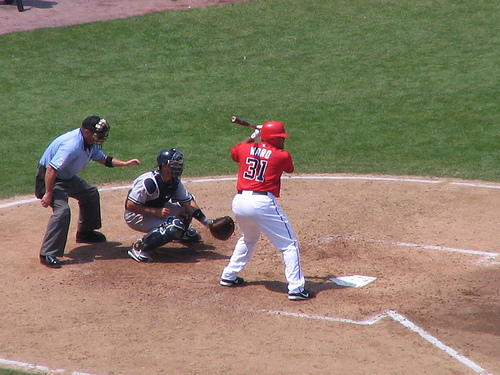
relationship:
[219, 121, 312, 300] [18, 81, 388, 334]
batter plays baseball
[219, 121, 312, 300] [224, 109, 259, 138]
batter holding bat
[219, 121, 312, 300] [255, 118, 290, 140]
batter wears helmet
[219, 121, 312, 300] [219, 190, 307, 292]
batter wears pants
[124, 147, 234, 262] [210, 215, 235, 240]
catcher holds glove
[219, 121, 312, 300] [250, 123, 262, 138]
batter wears glove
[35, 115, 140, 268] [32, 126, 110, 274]
ref wears suit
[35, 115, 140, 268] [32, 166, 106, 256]
ref wears pants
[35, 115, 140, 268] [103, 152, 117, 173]
ref wears wrist band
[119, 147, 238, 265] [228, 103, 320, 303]
catcher behind batter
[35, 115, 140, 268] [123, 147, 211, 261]
ref behind catcher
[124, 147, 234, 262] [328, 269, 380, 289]
catcher behind home plate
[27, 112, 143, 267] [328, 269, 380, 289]
ref behind home plate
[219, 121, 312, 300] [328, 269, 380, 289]
batter behind home plate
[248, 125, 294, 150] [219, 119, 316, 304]
helmet worn by batter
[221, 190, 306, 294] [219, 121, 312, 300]
pants worn by batter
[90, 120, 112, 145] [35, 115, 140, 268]
mask worn by ref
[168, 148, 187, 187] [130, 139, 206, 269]
mask worn by catcher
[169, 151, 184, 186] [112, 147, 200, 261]
mask worn by catcher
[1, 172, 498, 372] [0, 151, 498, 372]
dirt part of baseball diamond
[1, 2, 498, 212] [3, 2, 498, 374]
grass part of baseball field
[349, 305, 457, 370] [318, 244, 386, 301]
lines are part of baseball diamond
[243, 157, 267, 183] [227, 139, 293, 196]
31 are part of shirt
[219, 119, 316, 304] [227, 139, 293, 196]
batter wears shirt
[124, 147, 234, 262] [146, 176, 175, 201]
catcher wears pads